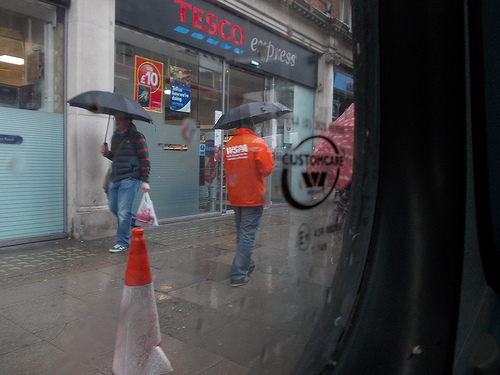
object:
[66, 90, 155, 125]
umbrella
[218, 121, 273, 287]
person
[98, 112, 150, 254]
person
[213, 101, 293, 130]
umbrella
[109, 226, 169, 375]
cone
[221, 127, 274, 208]
jacket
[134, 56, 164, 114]
sign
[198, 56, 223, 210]
window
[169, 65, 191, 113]
sign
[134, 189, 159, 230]
bag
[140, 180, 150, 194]
hand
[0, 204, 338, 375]
sidewalk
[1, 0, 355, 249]
building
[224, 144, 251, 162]
logo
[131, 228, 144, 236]
tip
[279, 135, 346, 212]
sticker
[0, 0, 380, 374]
window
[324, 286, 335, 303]
drop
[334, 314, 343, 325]
drop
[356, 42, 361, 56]
drop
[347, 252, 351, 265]
drop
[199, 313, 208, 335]
drop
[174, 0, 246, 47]
tescoe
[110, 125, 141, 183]
vest